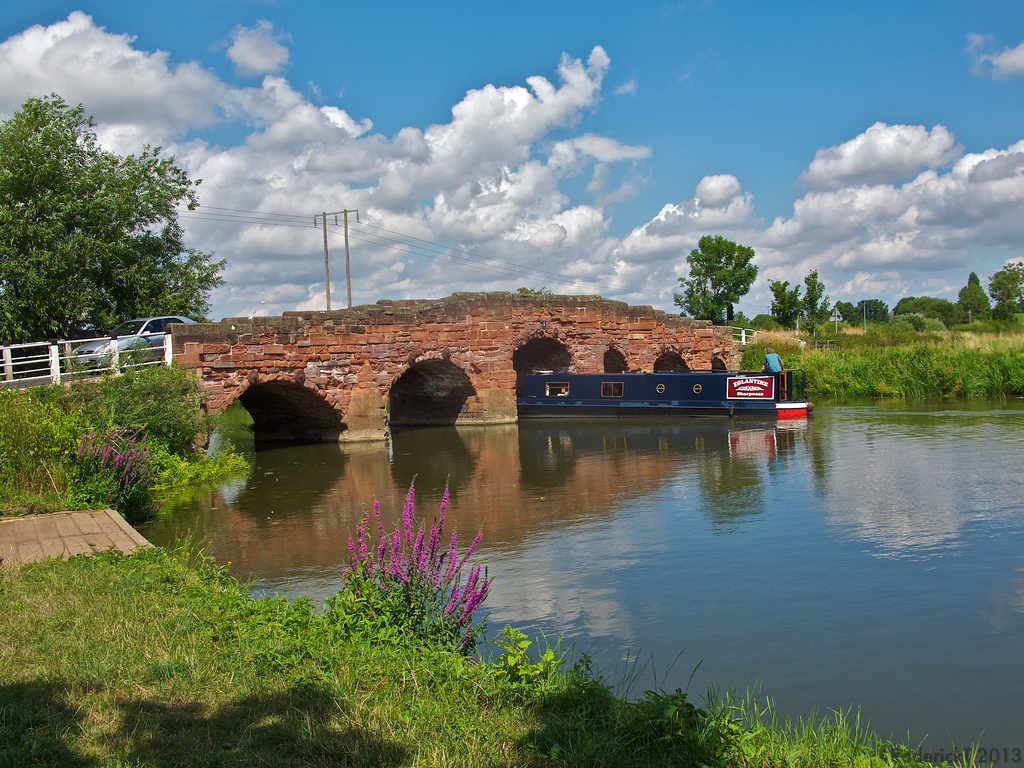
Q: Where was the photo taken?
A: On the river.